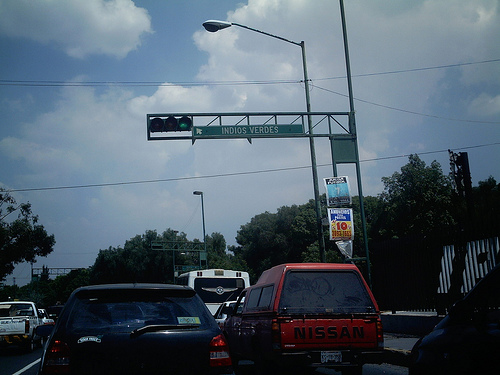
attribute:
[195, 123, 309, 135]
street sign — green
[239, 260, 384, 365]
car — red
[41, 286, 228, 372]
car — black, blue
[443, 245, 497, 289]
lettering — white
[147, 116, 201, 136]
traffic light — green, tall, signalling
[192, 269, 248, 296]
bus — white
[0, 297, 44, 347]
truck — white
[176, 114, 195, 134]
light — steel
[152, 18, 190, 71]
sky — blue